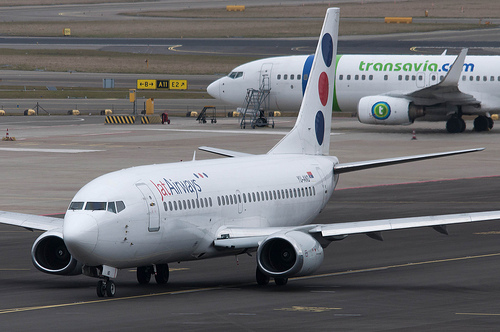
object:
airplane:
[0, 7, 499, 299]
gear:
[94, 279, 118, 296]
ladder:
[240, 86, 269, 132]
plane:
[207, 52, 499, 134]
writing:
[356, 60, 475, 72]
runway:
[1, 170, 500, 331]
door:
[259, 63, 274, 93]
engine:
[254, 228, 326, 279]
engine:
[30, 229, 77, 275]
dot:
[320, 32, 336, 67]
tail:
[268, 6, 344, 154]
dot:
[318, 72, 330, 107]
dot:
[313, 109, 326, 145]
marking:
[170, 80, 185, 89]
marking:
[157, 82, 170, 88]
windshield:
[67, 200, 126, 213]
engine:
[357, 94, 424, 124]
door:
[133, 182, 163, 231]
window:
[163, 201, 169, 213]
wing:
[217, 209, 498, 247]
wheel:
[445, 116, 467, 134]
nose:
[206, 75, 227, 102]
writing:
[150, 177, 203, 200]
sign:
[136, 77, 190, 91]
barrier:
[102, 112, 162, 125]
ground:
[1, 43, 271, 79]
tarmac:
[0, 117, 498, 213]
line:
[0, 249, 499, 316]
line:
[454, 310, 498, 320]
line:
[1, 118, 84, 125]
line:
[168, 42, 209, 54]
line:
[409, 45, 460, 53]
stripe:
[300, 49, 316, 96]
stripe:
[334, 54, 342, 112]